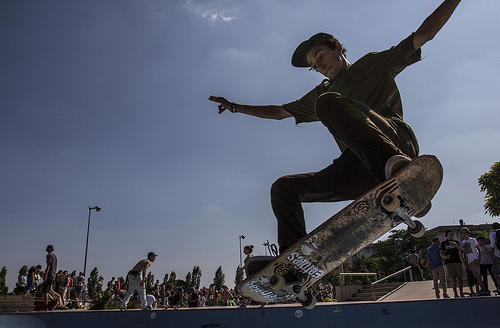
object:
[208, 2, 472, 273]
guy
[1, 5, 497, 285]
sky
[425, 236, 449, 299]
person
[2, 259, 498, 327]
skate park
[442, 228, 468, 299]
person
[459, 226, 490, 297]
person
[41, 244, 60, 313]
person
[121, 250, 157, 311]
person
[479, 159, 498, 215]
tree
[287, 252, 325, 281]
letters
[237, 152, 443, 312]
skateboard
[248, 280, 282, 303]
letters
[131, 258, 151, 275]
shirt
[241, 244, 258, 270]
girl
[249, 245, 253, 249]
bun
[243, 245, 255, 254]
hair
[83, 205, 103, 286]
street light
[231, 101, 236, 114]
watch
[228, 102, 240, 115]
wrist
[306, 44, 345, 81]
face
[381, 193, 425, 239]
wheels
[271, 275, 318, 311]
wheels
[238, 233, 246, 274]
light posts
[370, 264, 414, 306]
rails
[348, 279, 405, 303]
stairs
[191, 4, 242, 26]
cloud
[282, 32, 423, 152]
shirt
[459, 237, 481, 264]
shirt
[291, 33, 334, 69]
cap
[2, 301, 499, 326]
ground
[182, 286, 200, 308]
person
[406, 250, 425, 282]
person